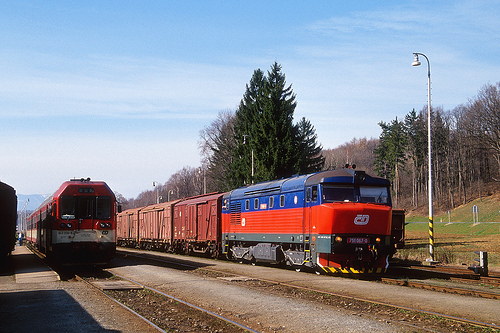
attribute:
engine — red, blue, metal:
[219, 161, 399, 278]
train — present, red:
[116, 161, 395, 279]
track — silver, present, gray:
[372, 257, 498, 307]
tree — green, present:
[217, 57, 321, 180]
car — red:
[170, 192, 222, 248]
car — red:
[137, 202, 177, 248]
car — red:
[113, 206, 141, 246]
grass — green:
[402, 204, 498, 238]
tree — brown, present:
[381, 111, 407, 207]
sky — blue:
[1, 1, 498, 160]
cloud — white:
[4, 63, 202, 117]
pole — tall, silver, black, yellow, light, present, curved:
[409, 50, 446, 272]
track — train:
[22, 239, 497, 327]